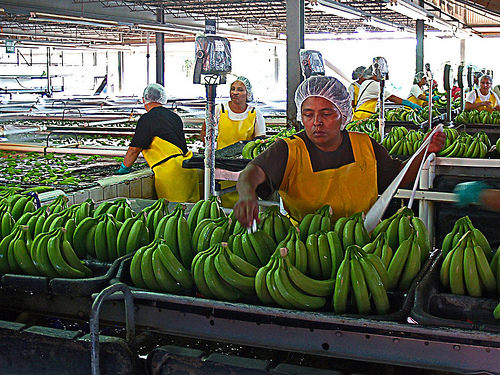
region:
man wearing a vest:
[267, 122, 402, 224]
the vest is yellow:
[275, 136, 393, 219]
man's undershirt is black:
[235, 129, 422, 217]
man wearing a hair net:
[287, 74, 359, 127]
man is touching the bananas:
[202, 56, 413, 246]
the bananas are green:
[9, 185, 489, 312]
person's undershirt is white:
[221, 96, 281, 146]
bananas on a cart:
[0, 171, 497, 342]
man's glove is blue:
[110, 157, 137, 177]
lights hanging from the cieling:
[301, 0, 483, 50]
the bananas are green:
[133, 225, 377, 293]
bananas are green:
[247, 258, 323, 303]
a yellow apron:
[160, 165, 188, 196]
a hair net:
[299, 83, 336, 96]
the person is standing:
[122, 87, 199, 195]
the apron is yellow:
[313, 178, 365, 198]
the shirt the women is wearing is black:
[265, 150, 285, 175]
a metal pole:
[89, 298, 111, 314]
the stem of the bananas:
[269, 248, 286, 258]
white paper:
[385, 185, 395, 199]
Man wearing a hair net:
[292, 71, 355, 129]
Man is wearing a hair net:
[289, 72, 362, 129]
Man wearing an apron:
[275, 126, 385, 229]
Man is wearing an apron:
[275, 126, 378, 221]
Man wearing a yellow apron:
[275, 127, 380, 217]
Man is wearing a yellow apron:
[276, 128, 381, 221]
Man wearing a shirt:
[250, 125, 406, 216]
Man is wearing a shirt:
[242, 127, 398, 197]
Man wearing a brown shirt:
[243, 128, 407, 200]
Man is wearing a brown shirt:
[242, 129, 412, 200]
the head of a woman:
[287, 68, 375, 169]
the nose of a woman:
[296, 103, 347, 139]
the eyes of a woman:
[298, 103, 341, 139]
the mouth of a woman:
[301, 115, 347, 147]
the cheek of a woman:
[293, 94, 398, 146]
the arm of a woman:
[211, 79, 299, 250]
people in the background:
[159, 4, 356, 160]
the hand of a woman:
[220, 186, 273, 252]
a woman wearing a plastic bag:
[290, 81, 380, 152]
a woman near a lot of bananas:
[198, 165, 326, 255]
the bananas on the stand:
[3, 186, 498, 322]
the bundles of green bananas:
[1, 191, 498, 333]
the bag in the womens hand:
[421, 122, 446, 161]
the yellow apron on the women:
[283, 133, 380, 213]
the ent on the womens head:
[288, 71, 352, 141]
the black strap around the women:
[141, 148, 184, 174]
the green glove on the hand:
[450, 180, 494, 208]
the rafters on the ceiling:
[116, 0, 432, 32]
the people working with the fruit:
[349, 62, 499, 127]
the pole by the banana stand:
[204, 83, 218, 210]